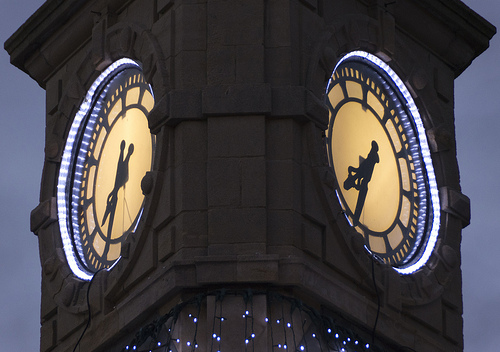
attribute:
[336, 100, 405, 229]
face — yellow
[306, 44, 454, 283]
clock — lit, round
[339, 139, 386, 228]
hands — black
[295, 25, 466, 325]
frame — brown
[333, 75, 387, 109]
marks — black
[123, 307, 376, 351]
lights — blue, small, bright, round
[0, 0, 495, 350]
tower — large, grey, black, dark, tall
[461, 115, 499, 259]
sky — dark blue, overcast, cloudy, blue, dark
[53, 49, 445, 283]
clocks — 2